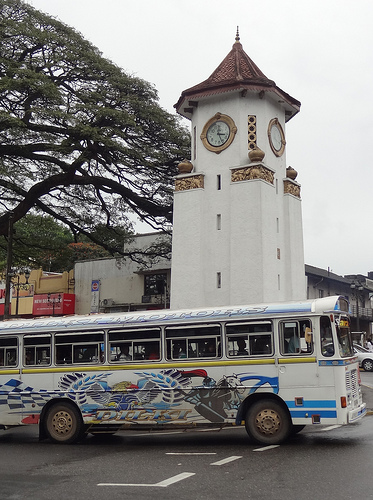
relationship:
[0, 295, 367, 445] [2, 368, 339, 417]
bus has design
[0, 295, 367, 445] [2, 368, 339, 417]
bus painted with design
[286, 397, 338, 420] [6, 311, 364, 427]
blue lines on bus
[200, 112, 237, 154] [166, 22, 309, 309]
clock on building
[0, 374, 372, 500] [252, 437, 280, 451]
ground with line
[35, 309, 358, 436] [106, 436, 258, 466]
bus on road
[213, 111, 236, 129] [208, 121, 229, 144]
ornate frame around clock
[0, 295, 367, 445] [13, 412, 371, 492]
bus on street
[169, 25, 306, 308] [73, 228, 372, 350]
clock tower on corner of building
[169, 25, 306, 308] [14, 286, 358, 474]
clock tower behind bus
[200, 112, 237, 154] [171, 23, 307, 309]
clock on left side of tower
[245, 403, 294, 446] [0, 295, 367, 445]
tire on bus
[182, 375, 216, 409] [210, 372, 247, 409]
knight on horse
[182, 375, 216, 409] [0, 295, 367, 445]
knight on side of bus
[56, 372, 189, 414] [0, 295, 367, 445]
image on side of bus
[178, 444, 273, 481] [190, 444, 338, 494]
lines on street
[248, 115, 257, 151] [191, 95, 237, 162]
design of clock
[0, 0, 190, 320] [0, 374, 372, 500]
large tree above ground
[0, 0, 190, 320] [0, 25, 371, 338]
large tree above building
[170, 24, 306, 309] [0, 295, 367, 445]
clock tower behind bus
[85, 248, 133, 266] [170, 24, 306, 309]
roof of clock tower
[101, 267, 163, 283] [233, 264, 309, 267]
line on road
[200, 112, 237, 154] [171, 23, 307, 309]
clock on tower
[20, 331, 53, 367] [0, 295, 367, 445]
window on bus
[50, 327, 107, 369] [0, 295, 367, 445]
window on bus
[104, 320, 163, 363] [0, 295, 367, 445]
window on bus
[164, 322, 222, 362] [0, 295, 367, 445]
passenger window on bus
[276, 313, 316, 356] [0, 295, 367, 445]
window on bus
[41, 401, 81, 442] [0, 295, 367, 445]
tire of bus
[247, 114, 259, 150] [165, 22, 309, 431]
design on clock tower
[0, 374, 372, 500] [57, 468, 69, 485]
ground has road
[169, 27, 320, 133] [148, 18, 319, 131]
roof has part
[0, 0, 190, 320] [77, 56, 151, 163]
large tree has part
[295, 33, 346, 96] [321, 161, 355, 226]
sky has part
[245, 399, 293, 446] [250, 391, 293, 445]
tire has part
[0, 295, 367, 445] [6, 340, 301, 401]
bus has side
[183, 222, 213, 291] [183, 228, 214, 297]
wall has part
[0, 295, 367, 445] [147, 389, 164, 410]
bus has edge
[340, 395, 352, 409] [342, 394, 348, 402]
light has part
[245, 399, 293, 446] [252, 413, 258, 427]
tire has edge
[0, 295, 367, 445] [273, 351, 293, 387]
bus has side